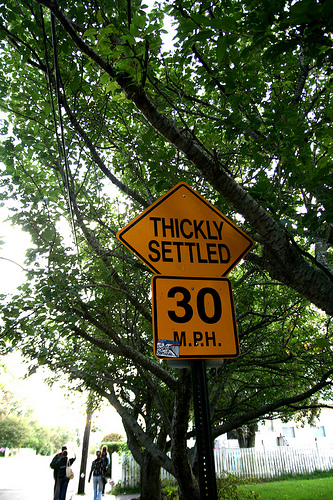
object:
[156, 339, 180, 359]
sticker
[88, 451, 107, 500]
person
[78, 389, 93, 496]
pole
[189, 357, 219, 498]
pole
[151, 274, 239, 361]
sign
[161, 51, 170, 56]
leaf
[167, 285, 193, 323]
number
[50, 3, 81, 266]
power line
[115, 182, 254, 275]
sign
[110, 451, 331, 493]
fence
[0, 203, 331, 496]
tree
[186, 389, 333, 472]
house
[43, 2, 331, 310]
branch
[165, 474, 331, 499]
grass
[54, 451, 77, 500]
person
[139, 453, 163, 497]
trunk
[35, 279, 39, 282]
leaf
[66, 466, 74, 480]
bag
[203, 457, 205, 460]
hole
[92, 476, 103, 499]
jeans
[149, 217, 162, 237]
writing